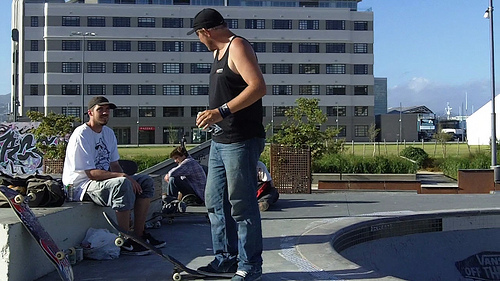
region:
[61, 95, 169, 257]
young man wearing white shirt and jean shorts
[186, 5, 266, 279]
man in black shirt on skateboard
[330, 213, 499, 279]
concrete skateboard ramp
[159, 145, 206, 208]
young man with plaid shirt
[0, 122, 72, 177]
black purple and blue graffiti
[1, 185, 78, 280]
skateboard with white wheels leaning against concrete wall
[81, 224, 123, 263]
white bag leaning against concrete wall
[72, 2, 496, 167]
large metal poles with streetlights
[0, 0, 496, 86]
blue sky with no clouds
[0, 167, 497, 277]
grey colored concrete around skateboard park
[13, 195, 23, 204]
the wheel on the skateboard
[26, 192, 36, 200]
the wheel on the skateboard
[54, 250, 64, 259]
the wheel on the skateboard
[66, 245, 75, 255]
the wheel on the skateboard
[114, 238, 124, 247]
the wheel on the skateboard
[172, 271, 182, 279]
the wheel on the skateboard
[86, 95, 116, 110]
the hat on the man's head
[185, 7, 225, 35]
the hat on the man's head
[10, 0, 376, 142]
the large building in the back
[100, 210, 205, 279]
the skateboard slanted upwards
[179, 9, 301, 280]
Man standing looking at sitting man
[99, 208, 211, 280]
Black skateboard with white wheels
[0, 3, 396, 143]
Tall grey and white building in the background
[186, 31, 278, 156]
Black tank top on man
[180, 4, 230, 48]
Black baseball hat on man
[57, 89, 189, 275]
Man sitting down on bench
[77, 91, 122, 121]
Black hat on man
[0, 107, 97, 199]
Graffiti on white wall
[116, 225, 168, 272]
Black and white nike shoes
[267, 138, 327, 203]
Small brown cage on sidewalk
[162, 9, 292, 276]
this is a person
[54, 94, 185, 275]
this is a person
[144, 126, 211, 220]
this is a person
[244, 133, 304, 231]
this is a person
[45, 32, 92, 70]
a window on a building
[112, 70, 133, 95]
a window on a building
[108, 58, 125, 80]
a window on a building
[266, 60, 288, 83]
a window on a building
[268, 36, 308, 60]
a window on a building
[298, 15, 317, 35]
a window on a building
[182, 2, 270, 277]
Man standing in the forefront.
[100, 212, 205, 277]
Black skateboard under the foot.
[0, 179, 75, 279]
Skate board leaning against the cement.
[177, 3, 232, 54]
Black hat on the man.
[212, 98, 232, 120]
Black band on the wrist.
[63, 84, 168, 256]
Person sitting on the concrete.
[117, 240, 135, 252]
Nike symbol on the shoe.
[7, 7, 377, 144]
Building in the background.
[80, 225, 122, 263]
White bag on the ground.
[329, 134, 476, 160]
Fence in the background.